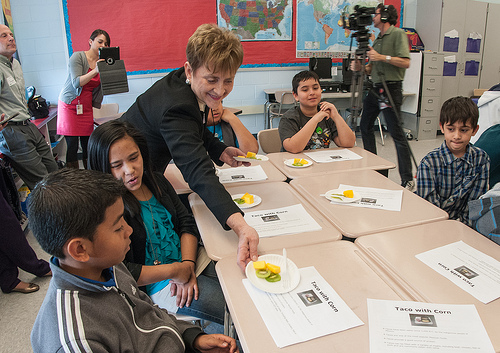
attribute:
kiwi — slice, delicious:
[255, 269, 271, 280]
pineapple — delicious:
[253, 261, 267, 270]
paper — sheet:
[414, 239, 499, 305]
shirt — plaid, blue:
[416, 139, 490, 227]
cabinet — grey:
[402, 49, 446, 141]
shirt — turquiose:
[138, 193, 182, 296]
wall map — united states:
[215, 2, 293, 42]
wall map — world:
[295, 0, 385, 59]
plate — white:
[284, 157, 315, 169]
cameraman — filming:
[350, 3, 414, 188]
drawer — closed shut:
[422, 74, 444, 97]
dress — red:
[56, 66, 101, 137]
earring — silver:
[185, 78, 192, 84]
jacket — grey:
[30, 254, 209, 352]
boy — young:
[26, 165, 241, 353]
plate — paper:
[245, 258, 302, 287]